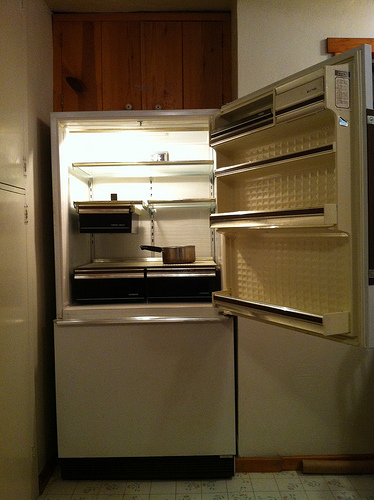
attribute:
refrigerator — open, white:
[56, 113, 217, 307]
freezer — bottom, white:
[62, 313, 239, 465]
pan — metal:
[148, 242, 196, 265]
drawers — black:
[203, 205, 205, 206]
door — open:
[212, 89, 349, 333]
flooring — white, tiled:
[256, 477, 301, 493]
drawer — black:
[142, 269, 221, 298]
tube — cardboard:
[292, 457, 364, 478]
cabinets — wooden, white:
[61, 9, 227, 107]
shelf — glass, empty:
[88, 164, 206, 178]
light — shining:
[84, 132, 144, 149]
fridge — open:
[45, 237, 224, 306]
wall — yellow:
[237, 177, 301, 197]